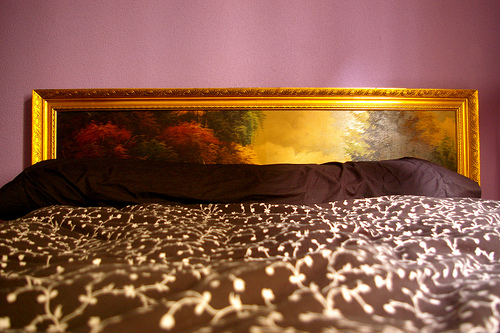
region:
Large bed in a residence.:
[10, 14, 497, 327]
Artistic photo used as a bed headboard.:
[20, 72, 487, 199]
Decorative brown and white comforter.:
[8, 172, 487, 330]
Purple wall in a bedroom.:
[7, 55, 498, 195]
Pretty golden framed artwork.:
[21, 80, 493, 148]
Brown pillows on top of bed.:
[24, 155, 477, 195]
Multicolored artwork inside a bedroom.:
[58, 112, 452, 157]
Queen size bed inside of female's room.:
[14, 168, 495, 329]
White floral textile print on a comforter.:
[159, 215, 466, 323]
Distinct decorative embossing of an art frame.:
[24, 80, 491, 115]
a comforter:
[154, 208, 431, 325]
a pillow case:
[21, 162, 464, 195]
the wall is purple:
[167, 8, 387, 65]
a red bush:
[169, 127, 219, 158]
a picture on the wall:
[38, 95, 473, 155]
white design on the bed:
[320, 257, 396, 305]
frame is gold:
[237, 85, 292, 105]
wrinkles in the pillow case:
[311, 161, 382, 193]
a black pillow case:
[208, 162, 309, 197]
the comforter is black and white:
[54, 207, 499, 307]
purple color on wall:
[205, 37, 314, 54]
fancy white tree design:
[280, 282, 378, 308]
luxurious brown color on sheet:
[251, 277, 283, 290]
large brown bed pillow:
[85, 152, 377, 202]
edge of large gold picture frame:
[458, 81, 482, 110]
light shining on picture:
[339, 74, 394, 116]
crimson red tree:
[155, 122, 225, 157]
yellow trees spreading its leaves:
[229, 135, 346, 158]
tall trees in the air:
[367, 112, 424, 148]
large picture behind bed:
[15, 69, 484, 316]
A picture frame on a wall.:
[22, 72, 486, 194]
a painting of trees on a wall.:
[55, 102, 265, 163]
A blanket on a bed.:
[0, 199, 492, 331]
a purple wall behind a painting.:
[0, 0, 497, 189]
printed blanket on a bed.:
[222, 226, 379, 291]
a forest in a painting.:
[54, 104, 267, 168]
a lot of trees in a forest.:
[346, 110, 459, 174]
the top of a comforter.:
[0, 153, 480, 226]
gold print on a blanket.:
[216, 259, 290, 305]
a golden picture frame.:
[25, 68, 63, 178]